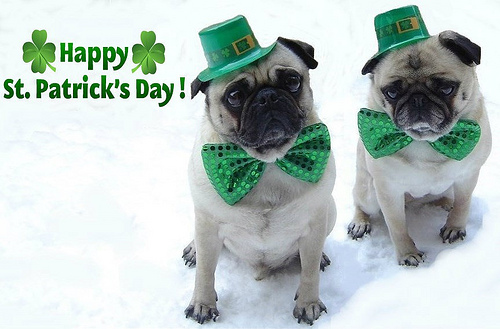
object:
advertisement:
[0, 0, 499, 328]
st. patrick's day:
[1, 69, 189, 111]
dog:
[175, 13, 340, 328]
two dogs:
[169, 1, 499, 328]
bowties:
[192, 123, 335, 206]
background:
[0, 0, 499, 326]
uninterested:
[175, 30, 499, 179]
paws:
[180, 298, 225, 326]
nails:
[293, 316, 305, 325]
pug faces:
[204, 47, 311, 168]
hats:
[193, 14, 281, 84]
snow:
[0, 0, 498, 328]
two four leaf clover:
[20, 29, 173, 76]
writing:
[134, 78, 150, 99]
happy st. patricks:
[2, 38, 188, 108]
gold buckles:
[229, 33, 259, 58]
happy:
[58, 39, 134, 74]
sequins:
[372, 126, 381, 136]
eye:
[273, 69, 306, 93]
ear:
[274, 33, 320, 70]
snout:
[241, 83, 288, 113]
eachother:
[168, 3, 494, 327]